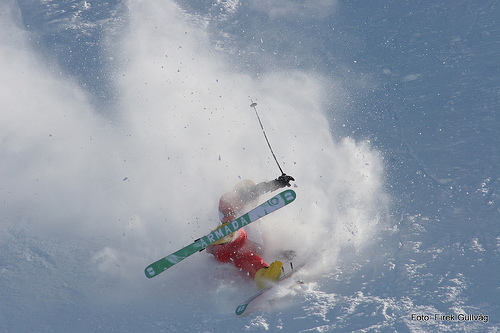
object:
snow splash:
[2, 1, 484, 332]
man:
[205, 173, 297, 291]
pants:
[205, 227, 271, 277]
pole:
[250, 99, 284, 174]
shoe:
[254, 260, 282, 291]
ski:
[142, 186, 296, 287]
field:
[5, 2, 495, 330]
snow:
[2, 3, 495, 332]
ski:
[144, 99, 357, 316]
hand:
[276, 173, 295, 187]